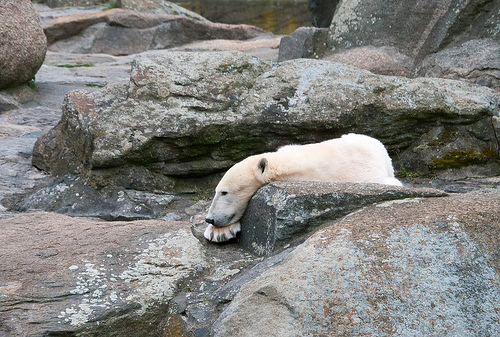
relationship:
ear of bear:
[255, 151, 277, 182] [212, 120, 404, 215]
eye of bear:
[221, 189, 229, 196] [202, 133, 407, 244]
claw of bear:
[201, 224, 242, 243] [202, 112, 444, 259]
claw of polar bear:
[201, 224, 242, 243] [196, 128, 414, 248]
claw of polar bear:
[201, 224, 242, 243] [204, 132, 403, 243]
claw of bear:
[218, 227, 230, 243] [202, 133, 407, 244]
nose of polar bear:
[201, 214, 215, 226] [196, 128, 414, 248]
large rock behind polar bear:
[30, 53, 495, 181] [204, 130, 404, 232]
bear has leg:
[202, 133, 407, 244] [198, 223, 240, 243]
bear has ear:
[202, 133, 407, 244] [247, 150, 278, 177]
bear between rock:
[202, 133, 407, 244] [241, 178, 440, 258]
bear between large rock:
[202, 133, 407, 244] [30, 51, 499, 188]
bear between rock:
[202, 133, 407, 244] [167, 187, 497, 334]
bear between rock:
[202, 133, 407, 244] [3, 206, 208, 334]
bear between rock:
[202, 133, 407, 244] [0, 168, 185, 223]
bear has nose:
[202, 133, 407, 244] [201, 209, 218, 226]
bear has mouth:
[203, 136, 400, 242] [209, 213, 240, 228]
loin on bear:
[296, 139, 371, 180] [186, 159, 274, 238]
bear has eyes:
[202, 133, 407, 244] [203, 184, 231, 204]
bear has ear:
[203, 136, 400, 242] [255, 157, 270, 184]